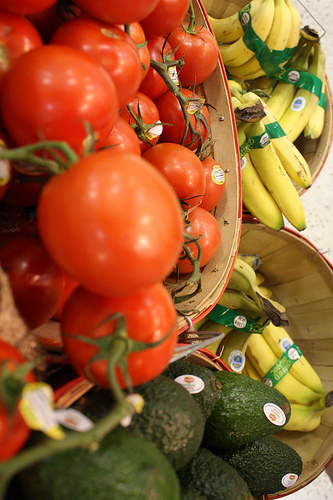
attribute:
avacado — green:
[40, 417, 175, 499]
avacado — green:
[136, 376, 204, 458]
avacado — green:
[193, 452, 244, 498]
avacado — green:
[220, 373, 288, 434]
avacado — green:
[181, 362, 219, 409]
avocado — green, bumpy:
[0, 420, 182, 498]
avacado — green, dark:
[226, 433, 303, 495]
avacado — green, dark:
[163, 359, 219, 420]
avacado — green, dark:
[77, 375, 205, 470]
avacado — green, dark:
[15, 417, 179, 498]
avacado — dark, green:
[176, 447, 253, 498]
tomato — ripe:
[144, 143, 205, 213]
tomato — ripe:
[173, 204, 221, 277]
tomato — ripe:
[167, 21, 221, 89]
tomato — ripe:
[48, 16, 141, 114]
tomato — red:
[0, 254, 120, 385]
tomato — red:
[160, 20, 221, 91]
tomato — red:
[44, 14, 147, 115]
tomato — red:
[149, 80, 213, 148]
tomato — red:
[136, 132, 208, 218]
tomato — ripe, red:
[37, 146, 184, 295]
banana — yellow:
[230, 85, 322, 236]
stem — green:
[3, 130, 90, 168]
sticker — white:
[256, 402, 293, 437]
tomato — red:
[141, 133, 212, 211]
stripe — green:
[288, 73, 328, 90]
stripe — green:
[277, 70, 327, 97]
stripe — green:
[271, 67, 328, 92]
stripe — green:
[203, 307, 266, 334]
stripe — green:
[250, 46, 290, 66]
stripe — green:
[250, 128, 280, 148]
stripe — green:
[265, 351, 300, 388]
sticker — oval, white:
[262, 398, 287, 428]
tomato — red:
[198, 147, 244, 215]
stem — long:
[0, 336, 146, 498]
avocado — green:
[205, 357, 283, 421]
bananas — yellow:
[220, 3, 332, 235]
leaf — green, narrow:
[125, 323, 187, 359]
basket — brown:
[242, 220, 332, 372]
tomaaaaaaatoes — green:
[33, 35, 261, 291]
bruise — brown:
[295, 169, 301, 178]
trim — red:
[195, 5, 242, 319]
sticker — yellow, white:
[211, 163, 224, 186]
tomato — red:
[59, 282, 178, 387]